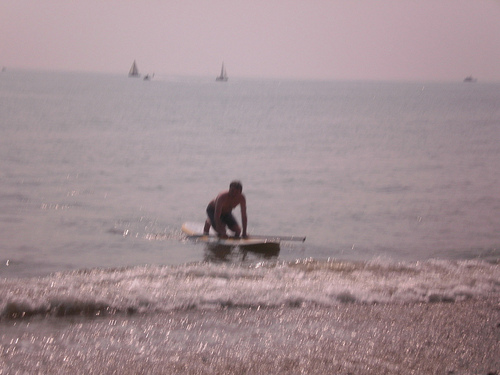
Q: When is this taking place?
A: Daytime.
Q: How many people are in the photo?
A: One.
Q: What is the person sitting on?
A: Surfboard.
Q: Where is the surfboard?
A: In the water.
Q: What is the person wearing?
A: Swim trunks.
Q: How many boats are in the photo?
A: Four.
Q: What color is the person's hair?
A: Black.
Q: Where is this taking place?
A: Ocean.